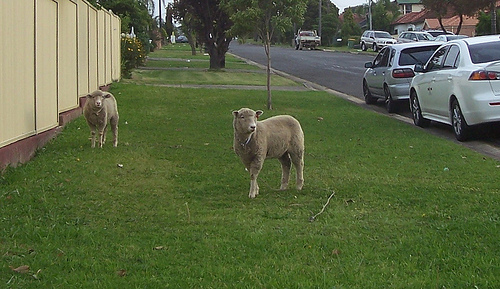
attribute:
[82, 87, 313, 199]
sheep — white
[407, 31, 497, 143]
car — white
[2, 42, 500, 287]
grass — green, strips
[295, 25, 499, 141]
cars — parked, background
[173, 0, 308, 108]
trees — background, growing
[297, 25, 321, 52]
truck — background, parked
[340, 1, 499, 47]
houses — background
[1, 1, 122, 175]
fence — colored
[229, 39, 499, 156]
street — black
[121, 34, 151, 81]
bush — green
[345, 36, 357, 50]
trash — standing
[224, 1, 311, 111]
tree — tall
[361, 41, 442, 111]
car — silver